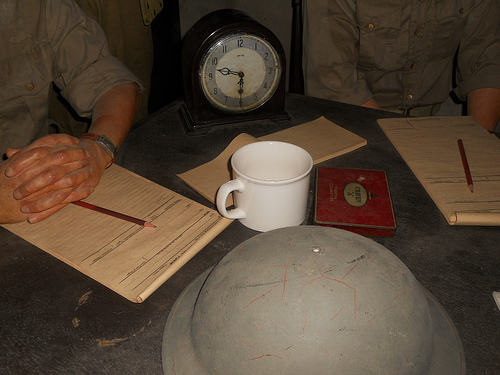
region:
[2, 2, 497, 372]
Interior, with old-fashioned elements, season unknown.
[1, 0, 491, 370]
Room with people, whether morning, or evening, unsure.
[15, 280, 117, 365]
Dark table surface with discolorations.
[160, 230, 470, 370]
Man's grey hat.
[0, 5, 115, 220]
Person, with folded hands on paper.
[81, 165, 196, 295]
Red pencil, with form.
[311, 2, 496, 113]
Second person, hands resting on lap.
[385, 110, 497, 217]
Paper and pencil on table.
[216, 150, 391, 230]
Red box and white mug.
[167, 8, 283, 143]
Old-fashioned mantle clock, showing 9: 30.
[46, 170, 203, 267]
the pencil is red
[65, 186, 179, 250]
the pencil is red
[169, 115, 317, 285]
the mug is white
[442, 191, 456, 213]
part of a table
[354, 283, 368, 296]
part of a plate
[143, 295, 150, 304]
part of a paper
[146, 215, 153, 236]
part of a pencil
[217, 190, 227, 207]
part of a handle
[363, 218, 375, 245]
part of a book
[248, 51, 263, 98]
part of a clock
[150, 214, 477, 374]
white construction hard hat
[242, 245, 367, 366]
orange marks on hard hat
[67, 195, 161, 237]
red pencil on pad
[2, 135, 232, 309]
paper pad on table top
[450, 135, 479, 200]
red pencil on right of photo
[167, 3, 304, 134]
wooden mantle clock on table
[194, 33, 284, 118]
gray and white clock face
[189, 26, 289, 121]
clock that reads nine thirty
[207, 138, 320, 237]
white ceramic coffee mug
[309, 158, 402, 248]
red rectangular box on table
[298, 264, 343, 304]
the aht is gray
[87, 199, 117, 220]
the pencil is red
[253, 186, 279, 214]
the cup is white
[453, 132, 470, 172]
the pencil is sitting on the paper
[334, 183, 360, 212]
the box is red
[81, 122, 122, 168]
he is wearing a watch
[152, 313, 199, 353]
the hat is on the table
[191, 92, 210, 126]
the clock is brown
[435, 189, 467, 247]
the paper is on the table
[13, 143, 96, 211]
he has his fingers interlocked